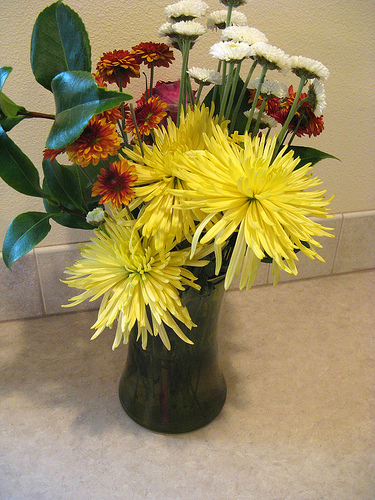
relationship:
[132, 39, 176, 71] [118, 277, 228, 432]
flower in vase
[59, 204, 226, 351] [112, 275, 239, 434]
flower inside vase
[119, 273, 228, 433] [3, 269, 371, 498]
glass vase on ground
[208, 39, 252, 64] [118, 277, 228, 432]
flower on vase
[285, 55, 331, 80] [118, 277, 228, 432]
flower on vase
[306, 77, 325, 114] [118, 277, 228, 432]
flower on vase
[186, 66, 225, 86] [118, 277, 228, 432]
flower on vase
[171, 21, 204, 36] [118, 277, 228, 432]
flower on vase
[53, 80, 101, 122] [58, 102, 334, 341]
leaves near flower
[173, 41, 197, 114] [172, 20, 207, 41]
green stem of flower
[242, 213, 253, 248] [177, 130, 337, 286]
petal of flower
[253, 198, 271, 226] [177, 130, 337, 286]
petal of flower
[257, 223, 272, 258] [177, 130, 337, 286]
petal of flower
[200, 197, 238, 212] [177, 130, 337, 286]
petal of flower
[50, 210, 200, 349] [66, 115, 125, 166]
petals of flower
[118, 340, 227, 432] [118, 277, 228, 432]
water inside vase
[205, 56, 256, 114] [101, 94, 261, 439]
flower in vase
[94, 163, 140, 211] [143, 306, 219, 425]
flower in vase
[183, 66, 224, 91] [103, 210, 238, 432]
flower in vase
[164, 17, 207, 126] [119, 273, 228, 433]
flower in glass vase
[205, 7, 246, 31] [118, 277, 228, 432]
flower in vase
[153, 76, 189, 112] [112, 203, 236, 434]
flower in vase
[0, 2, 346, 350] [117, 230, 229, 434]
floral arrangement in glass vase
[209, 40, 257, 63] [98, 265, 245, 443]
flower in vase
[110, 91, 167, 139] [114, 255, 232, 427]
flower in vase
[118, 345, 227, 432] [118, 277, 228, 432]
water in vase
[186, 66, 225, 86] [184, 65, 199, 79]
flower has petal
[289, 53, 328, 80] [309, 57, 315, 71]
flower has petal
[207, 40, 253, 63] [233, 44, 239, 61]
flower has petal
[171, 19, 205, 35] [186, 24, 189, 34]
flower has petal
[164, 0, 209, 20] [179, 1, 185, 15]
flower has petal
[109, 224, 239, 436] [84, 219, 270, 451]
flower in vase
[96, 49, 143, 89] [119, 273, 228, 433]
flower in glass vase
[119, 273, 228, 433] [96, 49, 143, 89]
glass vase with flower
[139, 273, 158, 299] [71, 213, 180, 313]
petal on flower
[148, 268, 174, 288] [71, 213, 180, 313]
petal on flower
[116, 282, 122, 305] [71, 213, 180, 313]
petal on flower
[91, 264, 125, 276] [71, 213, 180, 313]
petal on flower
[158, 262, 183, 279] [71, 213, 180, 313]
petal on flower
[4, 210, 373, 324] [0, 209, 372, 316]
tiles on lower wall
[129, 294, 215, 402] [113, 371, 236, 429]
flower stems on vase bottom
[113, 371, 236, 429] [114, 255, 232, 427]
vase bottom of vase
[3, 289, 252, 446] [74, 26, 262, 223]
shadow of flowers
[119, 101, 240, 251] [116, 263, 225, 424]
flower in vase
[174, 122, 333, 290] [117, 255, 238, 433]
flower in vase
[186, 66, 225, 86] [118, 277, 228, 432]
flower in vase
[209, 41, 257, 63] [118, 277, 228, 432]
flower in vase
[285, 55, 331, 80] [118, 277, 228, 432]
flower in vase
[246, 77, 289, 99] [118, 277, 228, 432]
flower in vase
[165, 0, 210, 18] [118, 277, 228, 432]
flower in vase